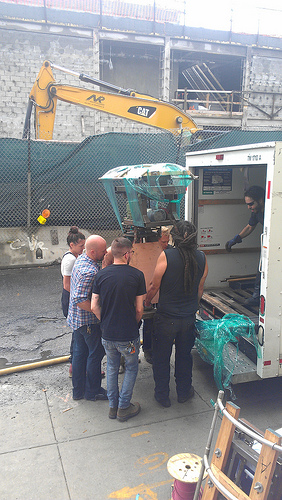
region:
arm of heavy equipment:
[21, 64, 202, 166]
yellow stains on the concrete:
[117, 423, 187, 496]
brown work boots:
[100, 386, 148, 422]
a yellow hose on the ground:
[8, 348, 58, 385]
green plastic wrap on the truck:
[188, 302, 259, 388]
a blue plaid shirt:
[59, 249, 114, 352]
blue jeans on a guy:
[90, 317, 159, 443]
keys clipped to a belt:
[123, 334, 145, 365]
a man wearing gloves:
[216, 226, 253, 264]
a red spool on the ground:
[147, 444, 220, 498]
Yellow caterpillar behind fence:
[21, 59, 204, 141]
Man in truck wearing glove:
[218, 186, 263, 307]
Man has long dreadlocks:
[143, 221, 206, 405]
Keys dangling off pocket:
[126, 340, 136, 355]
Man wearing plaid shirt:
[63, 233, 110, 401]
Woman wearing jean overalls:
[59, 223, 106, 378]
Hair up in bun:
[63, 226, 85, 246]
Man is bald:
[64, 235, 111, 401]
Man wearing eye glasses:
[88, 236, 148, 424]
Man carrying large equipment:
[88, 236, 143, 420]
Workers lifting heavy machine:
[60, 163, 202, 401]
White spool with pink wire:
[160, 442, 206, 499]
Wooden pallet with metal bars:
[189, 386, 277, 499]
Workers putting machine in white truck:
[181, 143, 281, 383]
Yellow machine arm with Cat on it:
[1, 3, 280, 144]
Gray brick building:
[1, 2, 280, 125]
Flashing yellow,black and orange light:
[11, 200, 55, 254]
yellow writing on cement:
[105, 429, 173, 499]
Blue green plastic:
[194, 312, 259, 367]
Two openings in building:
[96, 27, 252, 116]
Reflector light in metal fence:
[31, 204, 55, 227]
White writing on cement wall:
[7, 234, 54, 257]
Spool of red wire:
[162, 449, 201, 498]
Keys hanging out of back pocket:
[120, 339, 138, 357]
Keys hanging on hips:
[84, 324, 94, 340]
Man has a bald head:
[86, 232, 103, 259]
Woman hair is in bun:
[61, 223, 83, 245]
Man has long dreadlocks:
[169, 221, 200, 293]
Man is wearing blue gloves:
[222, 230, 246, 253]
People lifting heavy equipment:
[49, 167, 211, 404]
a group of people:
[18, 178, 270, 413]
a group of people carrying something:
[18, 159, 273, 362]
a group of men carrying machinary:
[42, 149, 280, 401]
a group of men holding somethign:
[51, 202, 275, 412]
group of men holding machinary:
[47, 126, 233, 356]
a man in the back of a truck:
[179, 150, 281, 268]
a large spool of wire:
[130, 417, 213, 498]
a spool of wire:
[122, 423, 222, 498]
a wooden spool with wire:
[155, 436, 220, 498]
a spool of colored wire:
[122, 434, 248, 498]